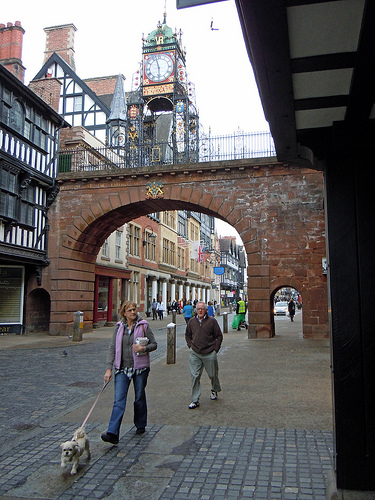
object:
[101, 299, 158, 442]
woman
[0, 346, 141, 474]
street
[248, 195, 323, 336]
wall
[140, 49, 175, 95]
clock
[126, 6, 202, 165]
tower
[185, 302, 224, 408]
man